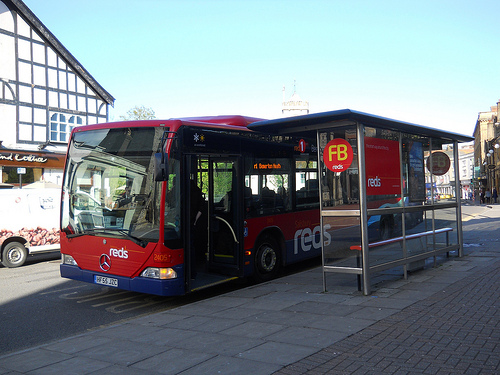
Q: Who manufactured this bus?
A: Mercedes Benz.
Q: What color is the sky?
A: Blue.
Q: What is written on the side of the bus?
A: Reds.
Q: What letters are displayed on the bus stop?
A: FB.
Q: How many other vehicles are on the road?
A: 1.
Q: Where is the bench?
A: In the bus stop shelter.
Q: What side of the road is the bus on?
A: The left.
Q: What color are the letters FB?
A: Yellow.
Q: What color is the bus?
A: Red and blue.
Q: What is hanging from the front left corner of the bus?
A: A mirror.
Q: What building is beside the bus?
A: Sidewalk.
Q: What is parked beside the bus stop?
A: Bus.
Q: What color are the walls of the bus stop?
A: Clear.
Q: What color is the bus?
A: Red and blue.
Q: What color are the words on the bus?
A: White.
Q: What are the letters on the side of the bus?
A: Read.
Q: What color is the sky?
A: Blue.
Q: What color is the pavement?
A: Gray.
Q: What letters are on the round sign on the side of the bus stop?
A: FB.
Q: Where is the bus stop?
A: Beside the bus.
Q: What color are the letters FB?
A: Yellow.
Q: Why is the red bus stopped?
A: So passengers can board and exit.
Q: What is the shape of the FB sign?
A: Circle.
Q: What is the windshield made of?
A: Glass.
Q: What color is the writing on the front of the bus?
A: White.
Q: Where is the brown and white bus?
A: Behind the red bus.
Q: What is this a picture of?
A: A bus stop.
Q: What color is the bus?
A: Red.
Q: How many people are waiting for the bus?
A: None.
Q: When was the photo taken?
A: Daytime.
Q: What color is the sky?
A: Blue.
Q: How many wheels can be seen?
A: Three.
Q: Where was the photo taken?
A: At a bus stop.